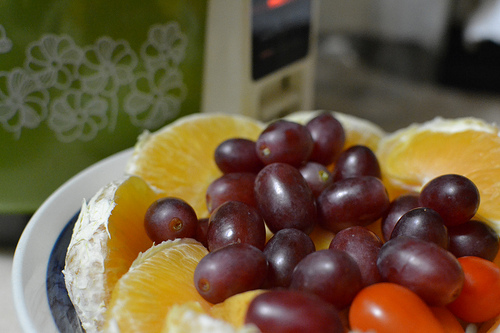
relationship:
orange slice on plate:
[62, 177, 172, 332] [13, 140, 151, 331]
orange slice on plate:
[103, 238, 210, 331] [13, 140, 151, 331]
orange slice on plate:
[132, 113, 267, 218] [13, 140, 151, 331]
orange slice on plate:
[270, 110, 385, 176] [13, 140, 151, 331]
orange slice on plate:
[375, 113, 499, 234] [13, 140, 151, 331]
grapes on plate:
[143, 111, 498, 332] [13, 140, 151, 331]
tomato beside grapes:
[349, 282, 442, 332] [143, 111, 498, 332]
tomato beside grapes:
[448, 255, 500, 317] [143, 111, 498, 332]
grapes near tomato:
[143, 111, 498, 332] [349, 282, 442, 332]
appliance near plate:
[199, 0, 319, 128] [13, 140, 151, 331]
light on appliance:
[267, 0, 289, 8] [199, 0, 319, 128]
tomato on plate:
[349, 282, 442, 332] [13, 140, 151, 331]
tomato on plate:
[448, 255, 500, 317] [13, 140, 151, 331]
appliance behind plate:
[199, 0, 319, 128] [13, 140, 151, 331]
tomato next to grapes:
[349, 282, 442, 332] [143, 111, 498, 332]